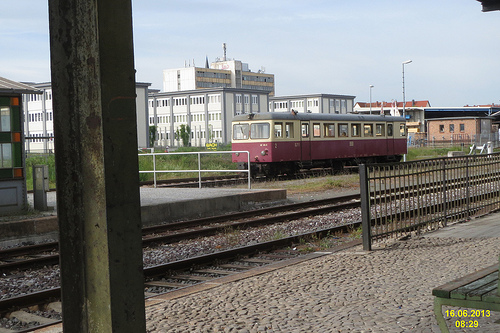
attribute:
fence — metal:
[355, 152, 493, 250]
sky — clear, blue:
[140, 2, 474, 51]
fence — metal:
[358, 150, 499, 255]